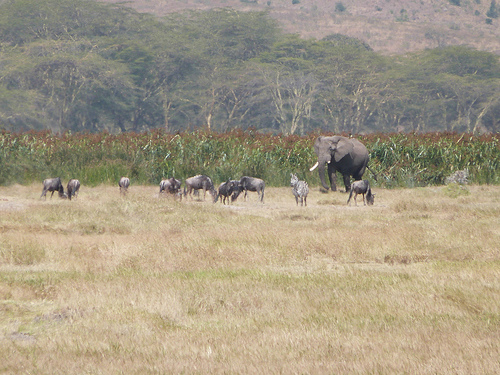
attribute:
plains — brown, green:
[371, 21, 477, 49]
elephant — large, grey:
[316, 132, 372, 199]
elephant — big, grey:
[309, 130, 370, 196]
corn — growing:
[88, 137, 173, 159]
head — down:
[200, 177, 221, 206]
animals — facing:
[36, 173, 88, 207]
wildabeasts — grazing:
[41, 170, 312, 211]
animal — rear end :
[115, 161, 169, 185]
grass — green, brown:
[20, 122, 284, 166]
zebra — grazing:
[346, 178, 378, 207]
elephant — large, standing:
[309, 131, 373, 208]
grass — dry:
[276, 213, 461, 373]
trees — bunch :
[0, 0, 498, 132]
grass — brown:
[1, 174, 499, 370]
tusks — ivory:
[309, 160, 321, 172]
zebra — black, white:
[272, 154, 349, 219]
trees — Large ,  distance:
[14, 34, 490, 238]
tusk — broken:
[307, 156, 318, 178]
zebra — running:
[287, 170, 310, 204]